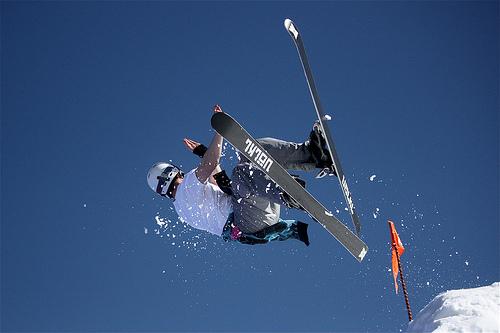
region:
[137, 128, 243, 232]
Skier with helmet.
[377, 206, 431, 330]
Orange flag on the snow.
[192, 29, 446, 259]
Skis on a skier.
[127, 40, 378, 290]
Skier jumping in the air.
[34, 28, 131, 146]
Blue sky in the background.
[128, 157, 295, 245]
Skier with white shirt.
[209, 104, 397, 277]
Black skies on skier.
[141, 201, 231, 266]
Snow flying in the air.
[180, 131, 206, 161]
Black gloves on person's hands.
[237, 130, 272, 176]
White lettering on skis.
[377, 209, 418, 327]
orange flag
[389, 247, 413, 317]
flag pole on snow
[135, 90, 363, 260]
a guy skiing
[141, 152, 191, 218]
a white helmet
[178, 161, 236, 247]
a white tee shirt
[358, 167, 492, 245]
snow flakes from the jump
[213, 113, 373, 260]
bottom of the ski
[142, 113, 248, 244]
a skier with short sleeve shirt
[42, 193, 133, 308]
blue sky in the background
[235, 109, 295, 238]
gray snow ski pants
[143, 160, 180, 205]
Silver helmet on the mans head.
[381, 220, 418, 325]
Orange flag on a pole.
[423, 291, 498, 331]
Chunk of snow on the right side.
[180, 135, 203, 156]
The mans left hand.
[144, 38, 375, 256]
The man in the air on skiis.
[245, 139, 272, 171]
The white writing on the mans skii.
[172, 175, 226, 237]
The mans white shirt.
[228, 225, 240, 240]
Pink fabric.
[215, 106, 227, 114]
The mans right finger tips.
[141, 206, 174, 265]
Snow in the air.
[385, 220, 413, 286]
Orange flag on metal rod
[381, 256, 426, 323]
Iron rod stuck in snow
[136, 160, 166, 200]
White helmet on snow skiing man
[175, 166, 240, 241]
White shirt on snow skiing person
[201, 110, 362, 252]
Black ski with white writing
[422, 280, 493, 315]
White snow pile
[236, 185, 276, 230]
Gray pants on legs of snow skier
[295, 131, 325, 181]
Black snow boot attached to ski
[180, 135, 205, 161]
Half glove on snow skier's hand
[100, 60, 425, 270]
Person on skis airborne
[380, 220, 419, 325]
A orange flag and pole in the snow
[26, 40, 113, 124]
A clear blue sky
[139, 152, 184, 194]
A white safety helmet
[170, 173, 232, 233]
A white tee shirt with short sleeves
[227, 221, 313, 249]
A gray and blue jacket toed around a person's waist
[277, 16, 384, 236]
The bottom of a ski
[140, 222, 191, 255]
White snow falling off of ski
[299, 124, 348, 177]
A foot attached to a ski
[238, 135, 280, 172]
The white logo on the bottom of a ski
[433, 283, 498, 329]
A mound of white snow